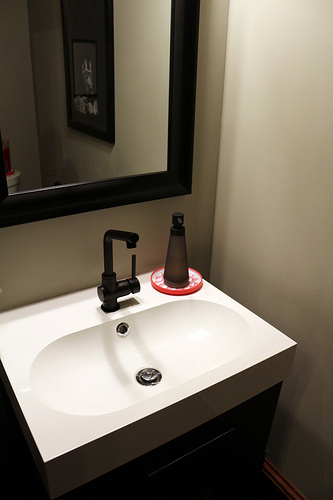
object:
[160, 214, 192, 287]
soap pump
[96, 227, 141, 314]
faucet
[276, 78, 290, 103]
wall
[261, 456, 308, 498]
trim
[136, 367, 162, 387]
drain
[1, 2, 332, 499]
wall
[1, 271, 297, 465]
counter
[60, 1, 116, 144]
picture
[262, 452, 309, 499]
moulding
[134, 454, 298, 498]
floor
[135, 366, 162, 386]
draine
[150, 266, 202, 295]
coaster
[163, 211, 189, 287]
bottle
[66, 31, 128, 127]
reflection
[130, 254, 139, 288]
handle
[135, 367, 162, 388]
hole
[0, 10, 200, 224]
mirror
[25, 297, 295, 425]
sink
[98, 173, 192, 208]
rim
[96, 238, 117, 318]
pipe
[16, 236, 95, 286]
paint